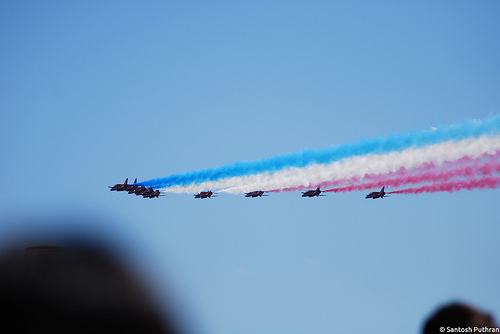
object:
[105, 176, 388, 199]
formation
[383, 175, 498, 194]
smoke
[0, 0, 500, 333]
clouds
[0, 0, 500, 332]
sky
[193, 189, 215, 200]
jets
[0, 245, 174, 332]
head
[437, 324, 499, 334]
writing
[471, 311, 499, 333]
corner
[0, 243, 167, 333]
person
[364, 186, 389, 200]
airplanes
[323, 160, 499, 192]
streams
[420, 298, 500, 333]
people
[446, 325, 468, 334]
santosh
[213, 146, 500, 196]
trails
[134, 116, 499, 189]
colors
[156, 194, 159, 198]
wings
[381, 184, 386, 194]
tails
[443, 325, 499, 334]
name